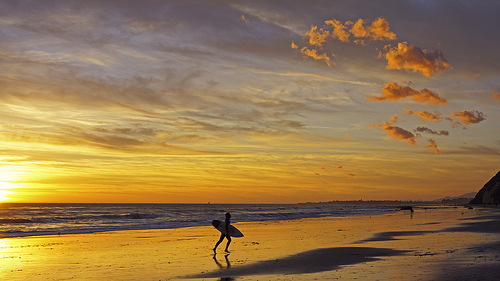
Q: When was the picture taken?
A: Sunset.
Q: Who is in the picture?
A: A woman.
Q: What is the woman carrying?
A: A surfboard.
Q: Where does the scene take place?
A: On the beach.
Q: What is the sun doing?
A: Setting.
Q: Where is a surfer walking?
A: On the beach.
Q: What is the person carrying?
A: A surfboard.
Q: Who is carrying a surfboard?
A: A person.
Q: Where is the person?
A: On the beach.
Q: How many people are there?
A: One.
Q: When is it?
A: Sunrise.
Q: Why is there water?
A: It is the beach.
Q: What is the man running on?
A: The shore.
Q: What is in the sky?
A: Clouds.